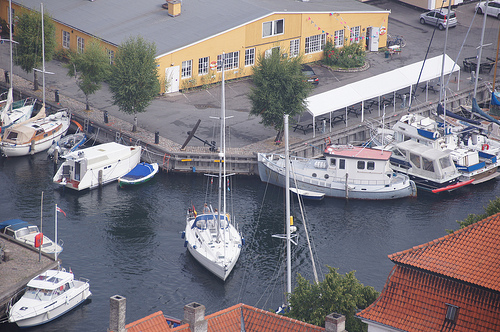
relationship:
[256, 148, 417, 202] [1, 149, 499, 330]
boat coming in from sea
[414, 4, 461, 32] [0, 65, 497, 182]
suv parked near pier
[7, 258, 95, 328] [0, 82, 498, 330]
boat at marina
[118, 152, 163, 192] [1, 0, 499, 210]
boat at marina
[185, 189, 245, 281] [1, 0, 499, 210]
boat at marina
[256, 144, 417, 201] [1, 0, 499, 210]
boat at marina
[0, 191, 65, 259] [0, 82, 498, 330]
boat at marina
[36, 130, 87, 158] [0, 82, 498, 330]
boat at marina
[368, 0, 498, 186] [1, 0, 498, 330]
boat at marina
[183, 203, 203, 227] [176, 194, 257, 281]
person at boat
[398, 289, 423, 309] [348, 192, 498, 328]
tiles on roof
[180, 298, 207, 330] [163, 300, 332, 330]
gray chimney on roof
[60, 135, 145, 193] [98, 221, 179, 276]
white boat in water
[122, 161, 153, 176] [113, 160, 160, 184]
cover on boat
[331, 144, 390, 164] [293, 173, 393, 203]
roof on boat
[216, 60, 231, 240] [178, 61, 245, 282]
mast of boat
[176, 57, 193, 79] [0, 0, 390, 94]
window on building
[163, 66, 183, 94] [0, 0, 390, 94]
door on building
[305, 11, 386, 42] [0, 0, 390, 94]
flags on building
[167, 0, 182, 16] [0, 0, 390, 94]
chimney on building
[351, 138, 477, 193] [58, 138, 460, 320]
boat at marina